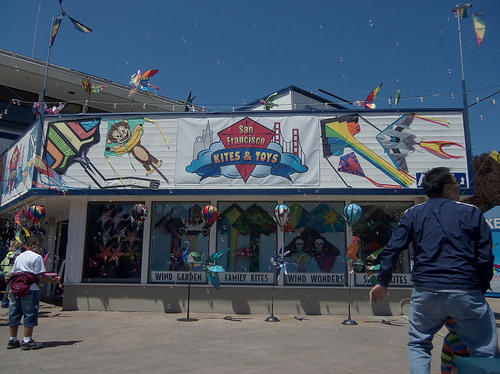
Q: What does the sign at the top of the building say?
A: San Francisco Kites & Toys.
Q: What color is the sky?
A: Blue.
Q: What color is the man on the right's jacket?
A: Blue.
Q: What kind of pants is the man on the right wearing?
A: Jeans.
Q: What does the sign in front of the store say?
A: San Francisco Kits & Toys.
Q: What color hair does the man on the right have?
A: Blue.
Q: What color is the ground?
A: Tan.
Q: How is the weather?
A: Sunny and clear.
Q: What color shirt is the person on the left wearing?
A: White.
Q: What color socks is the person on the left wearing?
A: White.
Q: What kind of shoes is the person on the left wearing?
A: Sneakers.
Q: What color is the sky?
A: Blue.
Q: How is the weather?
A: Clear and sunny.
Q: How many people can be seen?
A: Four.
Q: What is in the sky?
A: Bubbles.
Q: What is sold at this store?
A: Kites and toys.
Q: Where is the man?
A: Near the store.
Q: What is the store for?
A: Kites and toys.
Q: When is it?
A: Daytime.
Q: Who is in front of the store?
A: The people.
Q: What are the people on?
A: The ground.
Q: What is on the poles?
A: Kites.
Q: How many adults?
A: 2.